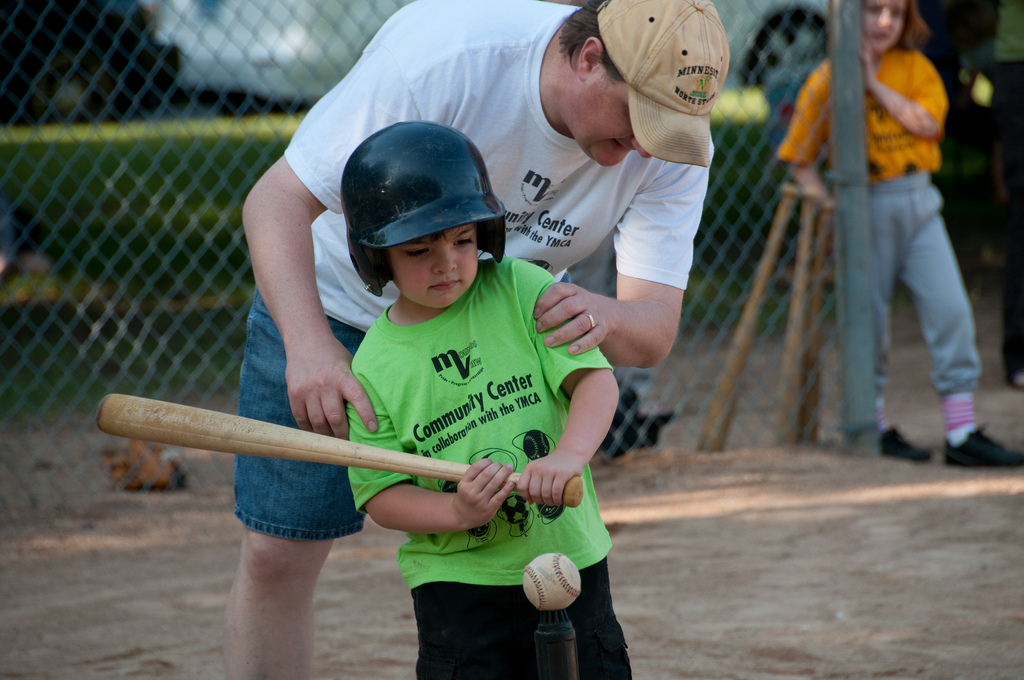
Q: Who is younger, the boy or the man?
A: The boy is younger than the man.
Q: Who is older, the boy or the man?
A: The man is older than the boy.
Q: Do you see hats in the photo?
A: Yes, there is a hat.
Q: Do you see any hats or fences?
A: Yes, there is a hat.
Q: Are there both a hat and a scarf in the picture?
A: No, there is a hat but no scarves.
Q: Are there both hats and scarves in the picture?
A: No, there is a hat but no scarves.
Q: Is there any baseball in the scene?
A: Yes, there is a baseball.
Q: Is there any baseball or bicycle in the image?
A: Yes, there is a baseball.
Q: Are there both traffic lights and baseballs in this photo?
A: No, there is a baseball but no traffic lights.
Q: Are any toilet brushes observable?
A: No, there are no toilet brushes.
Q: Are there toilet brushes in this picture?
A: No, there are no toilet brushes.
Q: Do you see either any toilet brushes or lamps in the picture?
A: No, there are no toilet brushes or lamps.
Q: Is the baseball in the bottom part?
A: Yes, the baseball is in the bottom of the image.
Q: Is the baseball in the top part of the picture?
A: No, the baseball is in the bottom of the image.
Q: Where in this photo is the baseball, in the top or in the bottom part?
A: The baseball is in the bottom of the image.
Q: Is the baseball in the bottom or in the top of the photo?
A: The baseball is in the bottom of the image.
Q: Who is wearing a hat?
A: The man is wearing a hat.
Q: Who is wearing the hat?
A: The man is wearing a hat.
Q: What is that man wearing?
A: The man is wearing a hat.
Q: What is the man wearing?
A: The man is wearing a hat.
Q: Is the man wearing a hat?
A: Yes, the man is wearing a hat.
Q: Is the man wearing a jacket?
A: No, the man is wearing a hat.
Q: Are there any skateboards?
A: No, there are no skateboards.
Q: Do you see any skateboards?
A: No, there are no skateboards.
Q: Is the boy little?
A: Yes, the boy is little.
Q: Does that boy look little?
A: Yes, the boy is little.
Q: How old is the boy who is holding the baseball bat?
A: The boy is little.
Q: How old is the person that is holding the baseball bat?
A: The boy is little.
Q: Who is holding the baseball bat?
A: The boy is holding the baseball bat.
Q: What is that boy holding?
A: The boy is holding the baseball bat.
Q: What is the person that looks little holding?
A: The boy is holding the baseball bat.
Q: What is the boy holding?
A: The boy is holding the baseball bat.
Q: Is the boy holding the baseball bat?
A: Yes, the boy is holding the baseball bat.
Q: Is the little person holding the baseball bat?
A: Yes, the boy is holding the baseball bat.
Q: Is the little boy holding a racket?
A: No, the boy is holding the baseball bat.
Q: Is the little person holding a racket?
A: No, the boy is holding the baseball bat.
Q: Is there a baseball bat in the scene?
A: Yes, there is a baseball bat.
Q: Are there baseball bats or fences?
A: Yes, there is a baseball bat.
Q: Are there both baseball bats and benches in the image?
A: No, there is a baseball bat but no benches.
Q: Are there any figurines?
A: No, there are no figurines.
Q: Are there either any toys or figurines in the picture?
A: No, there are no figurines or toys.